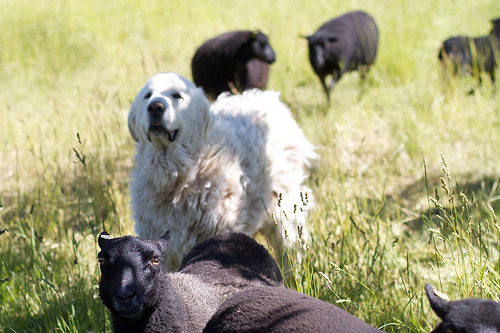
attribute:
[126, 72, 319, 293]
dog — fluffy, wooly, white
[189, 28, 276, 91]
sheep — shaved, black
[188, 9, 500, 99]
three sheep — shaved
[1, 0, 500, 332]
grass — tall, green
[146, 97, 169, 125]
nose — black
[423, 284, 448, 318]
ear — sticking up, black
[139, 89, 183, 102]
eyes — black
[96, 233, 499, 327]
sheep — shaved, black, together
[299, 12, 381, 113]
sheep — shaved, walking, black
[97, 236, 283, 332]
sheep — shaved, black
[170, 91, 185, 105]
eye — black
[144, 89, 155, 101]
eye — black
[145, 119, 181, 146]
mouth — black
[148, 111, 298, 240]
hair — blowing